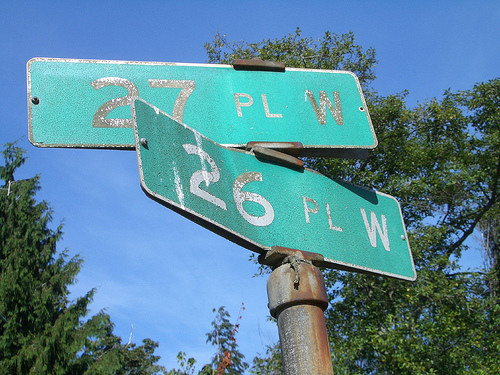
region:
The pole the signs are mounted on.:
[270, 257, 332, 374]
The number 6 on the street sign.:
[236, 154, 273, 231]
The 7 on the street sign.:
[152, 69, 198, 126]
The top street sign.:
[30, 51, 367, 150]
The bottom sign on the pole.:
[135, 97, 417, 278]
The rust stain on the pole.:
[286, 267, 336, 369]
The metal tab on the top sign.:
[232, 53, 287, 70]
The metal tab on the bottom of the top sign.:
[249, 141, 301, 147]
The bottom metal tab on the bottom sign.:
[270, 242, 324, 262]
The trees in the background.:
[4, 15, 492, 373]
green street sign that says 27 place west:
[24, 56, 381, 149]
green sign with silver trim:
[130, 96, 416, 281]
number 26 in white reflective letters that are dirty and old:
[182, 142, 274, 227]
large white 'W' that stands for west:
[357, 206, 390, 252]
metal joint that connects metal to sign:
[257, 246, 329, 318]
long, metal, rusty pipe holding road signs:
[274, 303, 336, 373]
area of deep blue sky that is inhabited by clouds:
[0, 1, 498, 149]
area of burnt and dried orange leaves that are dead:
[215, 348, 232, 373]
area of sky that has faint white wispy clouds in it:
[50, 210, 280, 373]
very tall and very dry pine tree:
[0, 134, 142, 374]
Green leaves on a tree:
[72, 339, 142, 366]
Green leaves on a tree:
[7, 327, 61, 365]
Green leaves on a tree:
[7, 293, 57, 342]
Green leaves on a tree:
[50, 291, 117, 358]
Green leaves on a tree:
[32, 240, 90, 285]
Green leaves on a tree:
[21, 196, 60, 247]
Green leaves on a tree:
[2, 132, 42, 223]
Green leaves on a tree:
[358, 321, 450, 358]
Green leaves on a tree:
[405, 123, 498, 256]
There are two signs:
[27, 48, 424, 283]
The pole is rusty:
[262, 245, 342, 370]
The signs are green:
[15, 50, 420, 280]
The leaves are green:
[402, 106, 497, 366]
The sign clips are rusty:
[228, 55, 298, 74]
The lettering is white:
[180, 145, 395, 251]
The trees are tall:
[0, 136, 137, 371]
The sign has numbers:
[177, 140, 282, 226]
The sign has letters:
[300, 193, 390, 250]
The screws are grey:
[29, 91, 46, 107]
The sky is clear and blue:
[57, 18, 193, 56]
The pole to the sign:
[253, 256, 368, 373]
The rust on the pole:
[290, 253, 337, 374]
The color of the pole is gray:
[271, 275, 316, 370]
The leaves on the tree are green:
[388, 313, 475, 359]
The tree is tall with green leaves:
[0, 156, 162, 373]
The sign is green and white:
[180, 143, 391, 248]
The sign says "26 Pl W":
[173, 137, 402, 257]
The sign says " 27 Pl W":
[92, 65, 349, 132]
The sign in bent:
[172, 127, 324, 256]